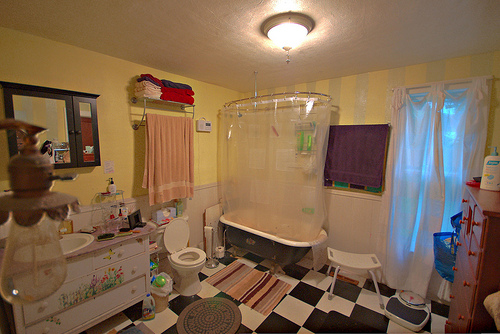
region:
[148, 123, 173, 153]
wrinkles on a towel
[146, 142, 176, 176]
wrinkles on a towel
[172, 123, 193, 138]
wrinkles on a towel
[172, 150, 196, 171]
wrinkles on a towel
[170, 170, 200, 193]
wrinkles on a towel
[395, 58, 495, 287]
blinds of a window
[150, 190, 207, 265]
cover of a toilet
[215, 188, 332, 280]
a bath tub of a restroom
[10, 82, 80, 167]
mirror on the wall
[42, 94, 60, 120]
reflection of the mirror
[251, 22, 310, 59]
the light of a big bathroom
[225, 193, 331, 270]
the bathtub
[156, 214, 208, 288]
the toilet of a big bathroom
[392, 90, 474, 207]
the window of a big bathroom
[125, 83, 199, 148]
the towel rack of a big bathroom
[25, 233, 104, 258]
the sink of a big bathroom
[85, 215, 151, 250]
the countertop of a big bathroom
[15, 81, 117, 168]
the mirror of a big bathroom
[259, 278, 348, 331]
the tile floor of a big bathroom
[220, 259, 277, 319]
the pink rug of a big bathroom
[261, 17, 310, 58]
The light on the ceiling.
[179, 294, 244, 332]
Circle rug on the bathroom floor.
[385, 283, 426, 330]
The scale.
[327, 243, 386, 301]
The white plastic shower chair.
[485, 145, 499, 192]
Blue and white bottle of lotion.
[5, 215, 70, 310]
The clear light bulb.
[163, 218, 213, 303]
The white toilet bowl.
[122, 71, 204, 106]
The towels on the shelf.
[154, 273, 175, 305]
The small trash can.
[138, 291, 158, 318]
Bottle of cleaning solution.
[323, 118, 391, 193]
the towel is purple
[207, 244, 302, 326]
rag on the floor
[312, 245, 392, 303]
stool on the floor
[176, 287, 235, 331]
mat on the floor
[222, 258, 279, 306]
rug on the floor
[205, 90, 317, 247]
shower curtain around the tub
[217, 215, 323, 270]
tub in the bathroom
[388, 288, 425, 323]
scale in the bathroom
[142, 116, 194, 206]
towel hanging on the rack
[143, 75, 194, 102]
towels in a rack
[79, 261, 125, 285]
flowers painted on the counter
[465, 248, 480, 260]
knob on the drawer